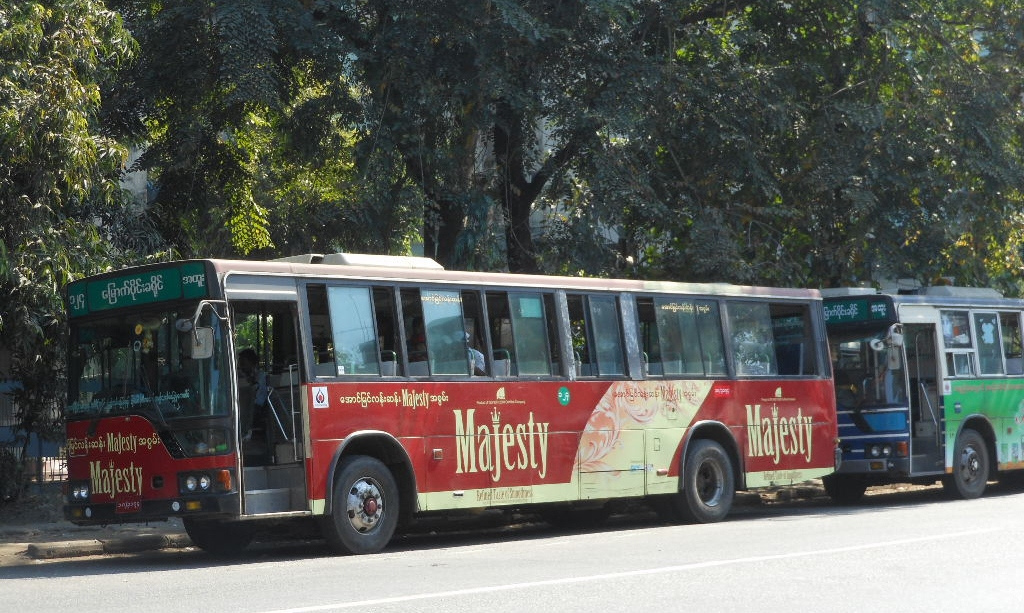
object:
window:
[421, 279, 476, 373]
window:
[488, 290, 567, 375]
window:
[296, 256, 406, 382]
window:
[649, 301, 725, 377]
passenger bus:
[25, 247, 844, 554]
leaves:
[47, 24, 130, 66]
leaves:
[361, 22, 413, 92]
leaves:
[570, 20, 633, 87]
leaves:
[829, 81, 914, 170]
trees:
[3, 5, 137, 403]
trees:
[295, 5, 493, 263]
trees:
[488, 7, 671, 273]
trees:
[788, 5, 998, 282]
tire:
[331, 450, 400, 556]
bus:
[824, 288, 1019, 503]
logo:
[451, 405, 566, 485]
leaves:
[789, 7, 906, 85]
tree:
[649, 0, 917, 251]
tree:
[622, 102, 811, 269]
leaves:
[673, 173, 760, 247]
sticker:
[550, 384, 577, 404]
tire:
[681, 435, 739, 526]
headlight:
[66, 485, 80, 505]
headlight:
[79, 487, 99, 507]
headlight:
[184, 472, 200, 498]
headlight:
[198, 472, 212, 494]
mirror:
[187, 304, 230, 365]